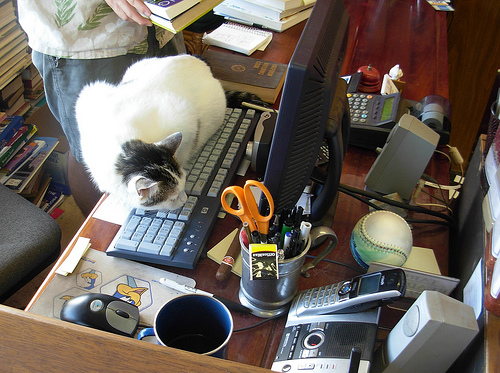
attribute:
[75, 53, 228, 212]
cat — black, white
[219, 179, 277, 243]
scissors — orange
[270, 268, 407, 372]
phone — land line, cordless, silver, black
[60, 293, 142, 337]
mouse — gray, black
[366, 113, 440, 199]
speaker — gray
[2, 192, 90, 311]
floor — wooden, brown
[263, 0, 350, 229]
monitor — flat, black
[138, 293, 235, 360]
cup — blue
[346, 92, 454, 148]
calculator — black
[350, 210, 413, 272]
ball — white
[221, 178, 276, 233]
handles — orange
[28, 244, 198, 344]
mouse pad — cartoon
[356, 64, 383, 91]
bell — red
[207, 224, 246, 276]
pad — yellow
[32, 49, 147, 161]
pants — gray